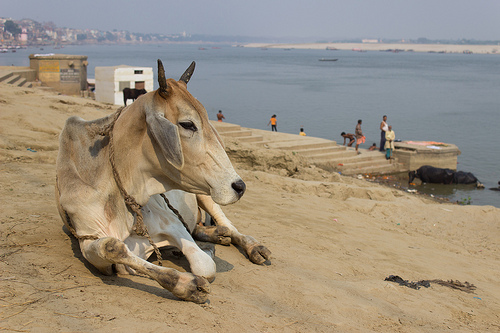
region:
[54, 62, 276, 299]
a tan cow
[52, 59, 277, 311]
a cow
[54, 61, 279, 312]
a cow lays in the sand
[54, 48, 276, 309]
a cow laying down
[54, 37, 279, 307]
the cow lays in the sand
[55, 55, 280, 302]
the cow has a rope around it's neck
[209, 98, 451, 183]
people by the water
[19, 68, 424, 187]
stone steps lead down to the water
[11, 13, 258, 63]
buildings beside the water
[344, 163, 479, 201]
garbage is in the water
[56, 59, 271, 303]
Cow laying down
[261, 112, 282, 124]
Pink shirt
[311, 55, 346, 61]
Boat in large body of water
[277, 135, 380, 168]
Set of stairs near water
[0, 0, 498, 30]
Dark blue sky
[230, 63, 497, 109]
Large body of water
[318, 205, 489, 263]
Tan dirt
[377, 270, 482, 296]
Dark debris on dirt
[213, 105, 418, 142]
People on steps near water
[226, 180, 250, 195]
Black nose on cow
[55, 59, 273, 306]
A cow lying on the sand near the water.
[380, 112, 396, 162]
Two people standing near the water.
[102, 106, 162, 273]
Thin brown rope wrapped around a cows neck.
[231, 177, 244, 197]
Black nose of a tan and white cow.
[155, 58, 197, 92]
Small horns on a cows head.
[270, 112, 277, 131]
Person in an orange shirt standing near water.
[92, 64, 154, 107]
White block building near the water.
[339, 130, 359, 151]
A person that is bent over near another person with orange shorts on.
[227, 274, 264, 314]
Lots of sand near the cow lying down.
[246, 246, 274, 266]
Back left hoof of a cow lying on the sand.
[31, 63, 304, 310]
animal is laying on the sand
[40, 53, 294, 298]
animal is awake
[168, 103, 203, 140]
animal's eyes are open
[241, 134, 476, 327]
sand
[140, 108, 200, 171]
ears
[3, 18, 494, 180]
body of water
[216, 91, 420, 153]
group of men are on the dock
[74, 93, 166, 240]
rope around the animal's neck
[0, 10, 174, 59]
group of buildings and trees in the distance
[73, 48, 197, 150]
white structure behind the animal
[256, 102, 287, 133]
person wearing a pink top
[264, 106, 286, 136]
person with dark brown hair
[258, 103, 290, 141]
person wearing dark pants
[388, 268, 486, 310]
dark plant in the sand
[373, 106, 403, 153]
people standing up on the dock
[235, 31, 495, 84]
coast in the distance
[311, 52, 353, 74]
large object in the water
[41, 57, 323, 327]
animal is laying in the sand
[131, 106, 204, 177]
large ears